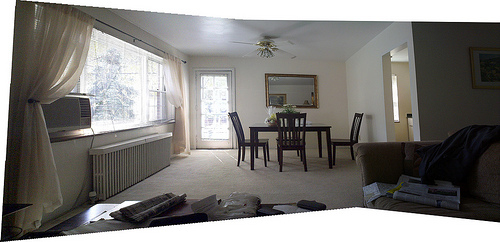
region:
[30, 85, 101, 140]
An air conditioner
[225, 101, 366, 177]
This is a dining table and chairs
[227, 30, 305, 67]
This is a ceiling fan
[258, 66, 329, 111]
A mirror is on the wall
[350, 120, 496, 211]
The couch has a blanket and papers on it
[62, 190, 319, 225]
A cluttered coffee table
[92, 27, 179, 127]
This is a large window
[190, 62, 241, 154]
This is a glass door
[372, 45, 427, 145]
Archway to another room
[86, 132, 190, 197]
This is a radiator heater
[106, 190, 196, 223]
A newspaper lays on the table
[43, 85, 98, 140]
An air conditioner in the window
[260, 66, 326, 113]
A large mirror on the wall beside the dining room table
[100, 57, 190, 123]
Sun shines in the window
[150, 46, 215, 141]
Gauzy white curtains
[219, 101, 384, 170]
Dark brown dining room table with four seats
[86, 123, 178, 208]
A radiator under the window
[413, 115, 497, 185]
A blanket thrown on the back of the couch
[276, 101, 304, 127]
Flowers on the table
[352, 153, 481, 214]
Books and papers on the couch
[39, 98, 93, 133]
Window air conditioning unit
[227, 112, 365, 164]
Dining room table and chairs.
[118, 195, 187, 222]
Newspaper on the table.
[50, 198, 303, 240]
Coffee table in the foreground.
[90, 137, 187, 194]
Radiator under the window.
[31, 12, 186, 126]
Giant picture window on the left side of the room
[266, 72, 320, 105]
Mirror over the dining room table.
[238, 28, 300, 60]
Ceiling fan and lights over the dining room table.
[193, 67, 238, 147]
Door to the backyard in dining room.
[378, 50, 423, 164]
Passageway to the kitchen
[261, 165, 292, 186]
part of the floor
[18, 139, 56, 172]
part of a curtain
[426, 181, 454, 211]
part of a magazine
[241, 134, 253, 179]
stand of a table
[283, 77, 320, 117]
part of a mirror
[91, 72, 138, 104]
part of a window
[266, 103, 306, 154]
part of a chair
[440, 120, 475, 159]
part of a cloth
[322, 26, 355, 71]
part of a ceiling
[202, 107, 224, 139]
part of a door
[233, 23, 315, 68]
white moving ceiling fan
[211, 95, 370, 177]
brown wooden dining set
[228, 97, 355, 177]
table with four chairs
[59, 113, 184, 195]
long white wall radiator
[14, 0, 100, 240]
see-through yellow curtains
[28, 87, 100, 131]
white window AC unit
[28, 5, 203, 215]
long windows letting in light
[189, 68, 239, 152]
white glass door with panes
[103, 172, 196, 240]
rolled up newspaper on desk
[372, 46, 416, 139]
wall opening without doors